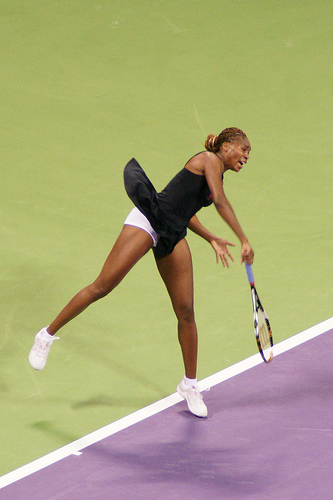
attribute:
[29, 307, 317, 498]
court — green , purple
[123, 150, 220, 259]
dress — black, flipped 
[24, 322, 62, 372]
tennis shoe — white 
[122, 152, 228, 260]
outfit — sports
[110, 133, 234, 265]
dress — sleeveless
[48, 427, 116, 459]
paint — white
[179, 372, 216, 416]
shoe — white, laced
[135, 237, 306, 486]
line — white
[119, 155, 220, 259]
black dress — black 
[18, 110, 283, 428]
woman tennis — playing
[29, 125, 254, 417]
woman — jumping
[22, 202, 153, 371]
leg — airborn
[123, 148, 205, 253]
dress — tennis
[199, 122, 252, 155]
hair — brown